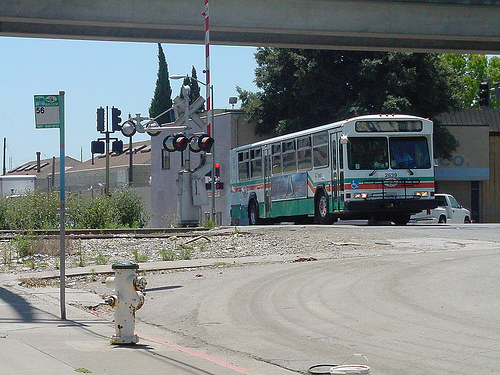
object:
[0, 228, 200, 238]
railroad tracks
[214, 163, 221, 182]
traffic signal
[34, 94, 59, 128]
sign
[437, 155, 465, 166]
sign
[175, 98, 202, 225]
pole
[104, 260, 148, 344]
fire hydrant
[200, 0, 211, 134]
barrier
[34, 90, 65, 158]
sign post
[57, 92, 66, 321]
pole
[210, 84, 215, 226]
pole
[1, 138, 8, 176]
pole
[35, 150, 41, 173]
pole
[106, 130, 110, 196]
pole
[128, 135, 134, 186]
pole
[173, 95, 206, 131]
sign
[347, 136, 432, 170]
windshield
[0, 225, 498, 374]
road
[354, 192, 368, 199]
headlights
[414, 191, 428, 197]
headlights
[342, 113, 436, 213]
front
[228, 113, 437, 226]
bus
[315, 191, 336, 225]
front wheel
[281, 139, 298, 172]
window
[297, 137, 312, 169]
window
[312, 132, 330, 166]
window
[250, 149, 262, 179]
window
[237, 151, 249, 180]
window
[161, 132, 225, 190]
lights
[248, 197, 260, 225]
wheel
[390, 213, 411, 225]
wheel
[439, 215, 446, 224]
wheel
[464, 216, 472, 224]
wheel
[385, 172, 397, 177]
number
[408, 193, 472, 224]
white pickup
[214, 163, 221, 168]
signal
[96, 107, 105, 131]
traffic signals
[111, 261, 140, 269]
cap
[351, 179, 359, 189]
handicap emblem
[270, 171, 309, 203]
sign